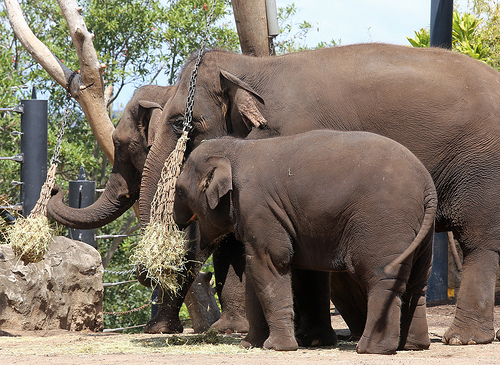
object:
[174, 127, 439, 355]
elephant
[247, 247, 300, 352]
leg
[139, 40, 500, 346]
elephant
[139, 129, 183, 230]
trunk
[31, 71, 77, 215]
chain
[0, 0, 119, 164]
tree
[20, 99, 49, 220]
fence post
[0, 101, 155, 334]
fence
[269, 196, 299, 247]
wrinkle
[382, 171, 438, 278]
tail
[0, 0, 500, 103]
sky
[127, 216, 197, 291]
hay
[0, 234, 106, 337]
boulder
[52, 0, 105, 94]
branch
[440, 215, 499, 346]
rear leg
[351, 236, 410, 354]
rear leg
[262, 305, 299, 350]
front foot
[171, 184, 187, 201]
eye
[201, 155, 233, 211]
ear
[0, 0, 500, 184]
background